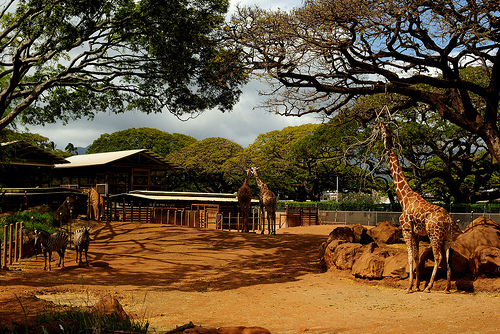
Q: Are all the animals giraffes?
A: No, there are both giraffes and zebras.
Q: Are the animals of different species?
A: Yes, they are giraffes and zebras.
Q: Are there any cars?
A: No, there are no cars.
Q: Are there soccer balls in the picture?
A: No, there are no soccer balls.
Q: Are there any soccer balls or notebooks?
A: No, there are no soccer balls or notebooks.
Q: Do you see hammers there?
A: No, there are no hammers.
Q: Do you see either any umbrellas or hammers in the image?
A: No, there are no hammers or umbrellas.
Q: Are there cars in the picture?
A: No, there are no cars.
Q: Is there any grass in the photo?
A: Yes, there is grass.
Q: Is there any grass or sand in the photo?
A: Yes, there is grass.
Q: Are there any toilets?
A: No, there are no toilets.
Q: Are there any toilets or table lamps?
A: No, there are no toilets or table lamps.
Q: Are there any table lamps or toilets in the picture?
A: No, there are no toilets or table lamps.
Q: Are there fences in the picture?
A: Yes, there is a fence.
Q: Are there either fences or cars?
A: Yes, there is a fence.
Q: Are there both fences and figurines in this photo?
A: No, there is a fence but no figurines.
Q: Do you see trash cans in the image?
A: No, there are no trash cans.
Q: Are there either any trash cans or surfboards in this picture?
A: No, there are no trash cans or surfboards.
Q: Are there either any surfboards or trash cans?
A: No, there are no trash cans or surfboards.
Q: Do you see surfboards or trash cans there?
A: No, there are no trash cans or surfboards.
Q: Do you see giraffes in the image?
A: Yes, there is a giraffe.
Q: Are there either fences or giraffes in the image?
A: Yes, there is a giraffe.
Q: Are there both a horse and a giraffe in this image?
A: No, there is a giraffe but no horses.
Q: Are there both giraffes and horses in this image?
A: No, there is a giraffe but no horses.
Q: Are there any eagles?
A: No, there are no eagles.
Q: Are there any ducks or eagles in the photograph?
A: No, there are no eagles or ducks.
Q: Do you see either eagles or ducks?
A: No, there are no eagles or ducks.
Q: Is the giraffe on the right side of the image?
A: Yes, the giraffe is on the right of the image.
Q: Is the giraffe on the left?
A: No, the giraffe is on the right of the image.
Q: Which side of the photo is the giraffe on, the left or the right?
A: The giraffe is on the right of the image.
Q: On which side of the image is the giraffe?
A: The giraffe is on the right of the image.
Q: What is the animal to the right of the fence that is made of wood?
A: The animal is a giraffe.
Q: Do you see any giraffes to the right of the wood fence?
A: Yes, there is a giraffe to the right of the fence.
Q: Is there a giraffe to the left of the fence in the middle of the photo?
A: No, the giraffe is to the right of the fence.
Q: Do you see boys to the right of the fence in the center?
A: No, there is a giraffe to the right of the fence.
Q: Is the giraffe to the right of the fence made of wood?
A: Yes, the giraffe is to the right of the fence.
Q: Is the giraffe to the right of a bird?
A: No, the giraffe is to the right of the fence.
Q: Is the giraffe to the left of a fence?
A: No, the giraffe is to the right of a fence.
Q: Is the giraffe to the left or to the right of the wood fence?
A: The giraffe is to the right of the fence.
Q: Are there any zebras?
A: Yes, there are zebras.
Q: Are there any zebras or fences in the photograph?
A: Yes, there are zebras.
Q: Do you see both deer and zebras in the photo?
A: No, there are zebras but no deer.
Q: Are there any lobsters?
A: No, there are no lobsters.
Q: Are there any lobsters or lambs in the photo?
A: No, there are no lobsters or lambs.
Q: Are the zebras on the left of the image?
A: Yes, the zebras are on the left of the image.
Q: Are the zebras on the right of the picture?
A: No, the zebras are on the left of the image.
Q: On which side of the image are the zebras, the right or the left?
A: The zebras are on the left of the image.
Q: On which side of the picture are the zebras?
A: The zebras are on the left of the image.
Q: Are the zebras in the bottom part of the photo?
A: Yes, the zebras are in the bottom of the image.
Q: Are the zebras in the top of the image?
A: No, the zebras are in the bottom of the image.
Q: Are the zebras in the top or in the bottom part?
A: The zebras are in the bottom of the image.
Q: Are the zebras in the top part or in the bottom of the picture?
A: The zebras are in the bottom of the image.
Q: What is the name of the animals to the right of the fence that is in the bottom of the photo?
A: The animals are zebras.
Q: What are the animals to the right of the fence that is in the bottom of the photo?
A: The animals are zebras.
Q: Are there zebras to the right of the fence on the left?
A: Yes, there are zebras to the right of the fence.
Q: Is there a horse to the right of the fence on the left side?
A: No, there are zebras to the right of the fence.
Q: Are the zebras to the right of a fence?
A: Yes, the zebras are to the right of a fence.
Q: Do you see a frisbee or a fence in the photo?
A: Yes, there is a fence.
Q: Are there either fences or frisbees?
A: Yes, there is a fence.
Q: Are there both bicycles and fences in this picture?
A: No, there is a fence but no bicycles.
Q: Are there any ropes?
A: No, there are no ropes.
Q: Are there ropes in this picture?
A: No, there are no ropes.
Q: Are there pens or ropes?
A: No, there are no ropes or pens.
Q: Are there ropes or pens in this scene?
A: No, there are no ropes or pens.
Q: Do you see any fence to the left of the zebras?
A: Yes, there is a fence to the left of the zebras.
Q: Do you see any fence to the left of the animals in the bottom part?
A: Yes, there is a fence to the left of the zebras.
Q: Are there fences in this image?
A: Yes, there is a fence.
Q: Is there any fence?
A: Yes, there is a fence.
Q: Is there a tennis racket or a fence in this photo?
A: Yes, there is a fence.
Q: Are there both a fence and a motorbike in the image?
A: No, there is a fence but no motorcycles.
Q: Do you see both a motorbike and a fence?
A: No, there is a fence but no motorcycles.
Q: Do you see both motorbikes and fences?
A: No, there is a fence but no motorcycles.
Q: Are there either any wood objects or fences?
A: Yes, there is a wood fence.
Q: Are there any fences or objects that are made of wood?
A: Yes, the fence is made of wood.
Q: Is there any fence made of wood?
A: Yes, there is a fence that is made of wood.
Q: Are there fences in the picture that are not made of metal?
A: Yes, there is a fence that is made of wood.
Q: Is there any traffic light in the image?
A: No, there are no traffic lights.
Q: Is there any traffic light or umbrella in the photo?
A: No, there are no traffic lights or umbrellas.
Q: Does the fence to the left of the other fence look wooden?
A: Yes, the fence is wooden.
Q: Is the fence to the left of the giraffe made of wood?
A: Yes, the fence is made of wood.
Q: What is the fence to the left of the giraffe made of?
A: The fence is made of wood.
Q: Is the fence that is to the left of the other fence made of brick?
A: No, the fence is made of wood.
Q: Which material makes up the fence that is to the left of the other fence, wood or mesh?
A: The fence is made of wood.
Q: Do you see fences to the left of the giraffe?
A: Yes, there is a fence to the left of the giraffe.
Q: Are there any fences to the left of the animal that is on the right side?
A: Yes, there is a fence to the left of the giraffe.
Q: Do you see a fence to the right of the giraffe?
A: No, the fence is to the left of the giraffe.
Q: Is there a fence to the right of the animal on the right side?
A: No, the fence is to the left of the giraffe.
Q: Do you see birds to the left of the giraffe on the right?
A: No, there is a fence to the left of the giraffe.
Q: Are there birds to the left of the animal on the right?
A: No, there is a fence to the left of the giraffe.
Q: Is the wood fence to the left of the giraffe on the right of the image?
A: Yes, the fence is to the left of the giraffe.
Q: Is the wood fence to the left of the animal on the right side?
A: Yes, the fence is to the left of the giraffe.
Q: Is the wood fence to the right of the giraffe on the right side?
A: No, the fence is to the left of the giraffe.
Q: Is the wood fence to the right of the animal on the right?
A: No, the fence is to the left of the giraffe.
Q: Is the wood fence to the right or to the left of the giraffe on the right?
A: The fence is to the left of the giraffe.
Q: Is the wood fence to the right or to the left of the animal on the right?
A: The fence is to the left of the giraffe.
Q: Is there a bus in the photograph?
A: No, there are no buses.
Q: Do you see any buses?
A: No, there are no buses.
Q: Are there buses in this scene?
A: No, there are no buses.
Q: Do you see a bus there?
A: No, there are no buses.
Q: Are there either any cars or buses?
A: No, there are no buses or cars.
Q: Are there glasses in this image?
A: No, there are no glasses.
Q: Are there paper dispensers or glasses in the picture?
A: No, there are no glasses or paper dispensers.